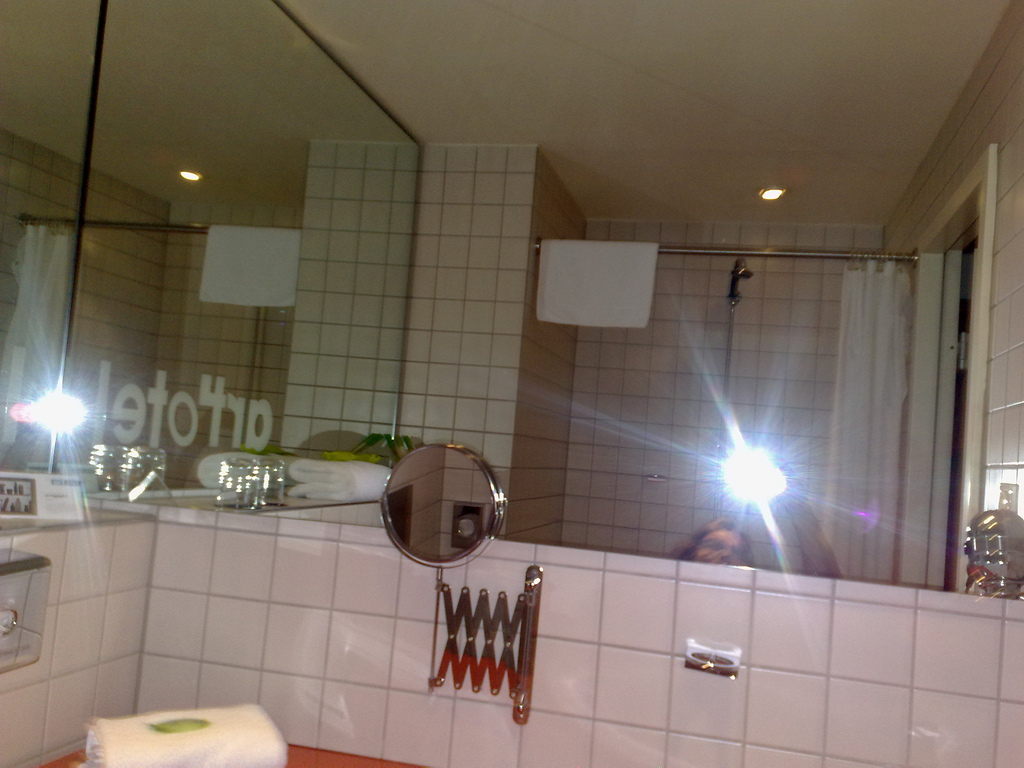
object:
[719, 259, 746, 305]
shower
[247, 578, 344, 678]
tile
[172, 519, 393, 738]
wall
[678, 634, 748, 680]
dish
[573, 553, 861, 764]
wall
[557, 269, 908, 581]
flash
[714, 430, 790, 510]
camera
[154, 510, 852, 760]
wall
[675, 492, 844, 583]
person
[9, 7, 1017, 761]
picture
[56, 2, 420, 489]
mirror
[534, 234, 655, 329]
towel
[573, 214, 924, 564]
area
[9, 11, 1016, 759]
photo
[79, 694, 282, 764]
towels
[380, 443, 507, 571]
mirror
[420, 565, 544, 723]
holder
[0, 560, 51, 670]
tissue box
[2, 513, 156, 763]
wall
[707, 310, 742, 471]
waterline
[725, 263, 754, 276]
shower head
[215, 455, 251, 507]
glass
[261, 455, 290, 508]
glass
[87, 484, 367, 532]
shelf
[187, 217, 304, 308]
towel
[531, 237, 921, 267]
curtain rod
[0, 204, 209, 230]
curtain rod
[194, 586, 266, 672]
tiles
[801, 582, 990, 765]
wall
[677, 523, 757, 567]
head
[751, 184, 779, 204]
circle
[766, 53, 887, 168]
ceiling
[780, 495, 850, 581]
arm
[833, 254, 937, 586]
curtains